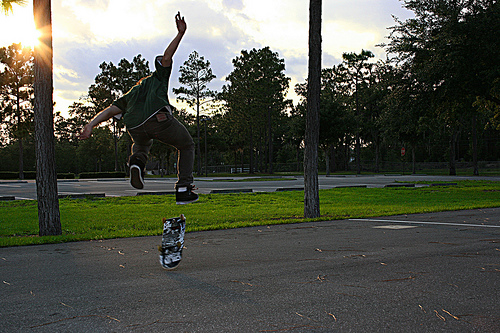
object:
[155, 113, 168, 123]
tag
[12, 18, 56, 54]
sun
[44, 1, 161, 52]
clouds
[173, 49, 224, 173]
tree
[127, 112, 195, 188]
jeans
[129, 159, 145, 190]
shoes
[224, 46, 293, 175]
tree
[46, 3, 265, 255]
man jumping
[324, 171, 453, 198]
ground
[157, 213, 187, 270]
skateboard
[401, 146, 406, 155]
stop sign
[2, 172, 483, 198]
parking lot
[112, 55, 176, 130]
shirt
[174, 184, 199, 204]
shoes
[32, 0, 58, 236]
trunk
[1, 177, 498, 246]
median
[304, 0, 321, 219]
tree trunk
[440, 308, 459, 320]
sticks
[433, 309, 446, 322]
sticks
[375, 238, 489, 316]
asphalt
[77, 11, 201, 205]
boy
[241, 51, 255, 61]
leaves